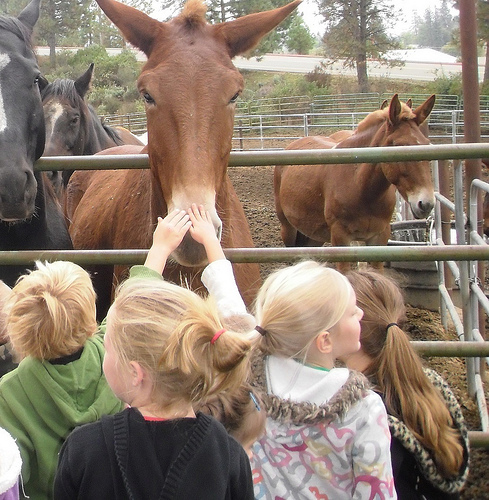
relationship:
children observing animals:
[8, 250, 469, 493] [76, 16, 272, 240]